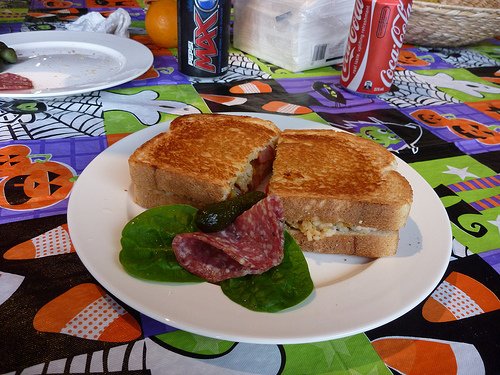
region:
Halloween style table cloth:
[19, 123, 66, 360]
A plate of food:
[85, 104, 442, 371]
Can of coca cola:
[333, 2, 444, 141]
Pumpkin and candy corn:
[7, 158, 102, 350]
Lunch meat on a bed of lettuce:
[126, 206, 323, 326]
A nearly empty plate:
[5, 12, 156, 89]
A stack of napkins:
[231, 2, 347, 76]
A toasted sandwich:
[146, 107, 420, 249]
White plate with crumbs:
[46, 36, 141, 96]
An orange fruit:
[144, 5, 179, 40]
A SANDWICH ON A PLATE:
[120, 99, 460, 339]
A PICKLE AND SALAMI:
[168, 197, 293, 290]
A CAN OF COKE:
[328, 7, 432, 102]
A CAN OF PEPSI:
[159, 3, 250, 89]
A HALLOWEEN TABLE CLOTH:
[4, 83, 199, 325]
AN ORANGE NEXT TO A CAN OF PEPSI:
[139, 6, 250, 86]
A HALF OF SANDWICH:
[266, 119, 435, 269]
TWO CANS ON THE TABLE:
[162, 1, 434, 103]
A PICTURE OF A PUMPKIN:
[1, 134, 84, 224]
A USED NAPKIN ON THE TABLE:
[60, 6, 142, 41]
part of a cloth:
[421, 111, 473, 157]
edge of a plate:
[338, 317, 364, 345]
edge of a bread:
[334, 224, 366, 267]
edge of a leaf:
[270, 290, 294, 312]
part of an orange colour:
[416, 350, 442, 365]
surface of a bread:
[162, 138, 213, 185]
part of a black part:
[466, 316, 486, 340]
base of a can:
[344, 73, 379, 112]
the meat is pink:
[182, 199, 288, 294]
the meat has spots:
[166, 187, 293, 287]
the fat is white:
[158, 189, 303, 292]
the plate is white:
[58, 82, 468, 374]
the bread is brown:
[126, 100, 266, 223]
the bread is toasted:
[151, 93, 261, 216]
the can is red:
[353, 0, 415, 107]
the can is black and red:
[158, 0, 233, 81]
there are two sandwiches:
[126, 92, 416, 261]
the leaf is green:
[113, 205, 191, 279]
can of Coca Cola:
[339, 0, 411, 92]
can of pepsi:
[177, 1, 229, 76]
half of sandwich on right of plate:
[268, 129, 413, 254]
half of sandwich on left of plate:
[128, 112, 278, 205]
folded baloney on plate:
[173, 196, 285, 281]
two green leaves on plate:
[116, 201, 314, 311]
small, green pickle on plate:
[194, 185, 266, 235]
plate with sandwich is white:
[66, 112, 453, 342]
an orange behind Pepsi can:
[146, 0, 183, 47]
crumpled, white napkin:
[64, 7, 131, 36]